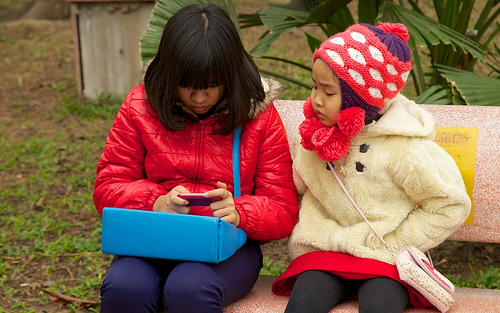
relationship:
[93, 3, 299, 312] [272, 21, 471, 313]
girl sitting next to child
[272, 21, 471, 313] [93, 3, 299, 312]
child sitting next to girl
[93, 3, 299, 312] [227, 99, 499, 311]
girl sitting on bench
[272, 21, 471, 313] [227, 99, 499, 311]
child sitting on bench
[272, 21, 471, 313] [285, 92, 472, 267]
child wearing jacket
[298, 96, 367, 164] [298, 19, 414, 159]
tie on hat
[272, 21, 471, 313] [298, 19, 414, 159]
child wearing hat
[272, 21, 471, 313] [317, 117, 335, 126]
child has chin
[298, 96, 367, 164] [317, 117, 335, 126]
tie beneath chin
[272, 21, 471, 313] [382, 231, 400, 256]
child has hand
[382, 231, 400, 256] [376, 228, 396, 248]
hand in pocket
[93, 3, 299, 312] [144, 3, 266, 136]
girl has hair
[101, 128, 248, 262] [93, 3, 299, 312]
purse on girl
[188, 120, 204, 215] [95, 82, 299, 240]
zipper zipped up on jacket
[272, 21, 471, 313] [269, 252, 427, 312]
child wearing skirt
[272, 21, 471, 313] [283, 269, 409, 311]
child wearing leggings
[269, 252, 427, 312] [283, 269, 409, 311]
skirt worn over leggings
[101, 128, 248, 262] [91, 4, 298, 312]
purse on woman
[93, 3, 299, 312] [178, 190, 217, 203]
girl holding cellphone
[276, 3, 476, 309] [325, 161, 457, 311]
child wearing purse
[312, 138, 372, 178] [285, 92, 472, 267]
buttons on jacket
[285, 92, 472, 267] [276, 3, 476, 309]
jacket on child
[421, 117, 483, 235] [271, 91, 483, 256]
sign on back of bench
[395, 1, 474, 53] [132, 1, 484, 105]
leaves on plant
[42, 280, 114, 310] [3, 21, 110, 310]
leaf laying on ground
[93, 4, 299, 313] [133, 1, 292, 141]
girl with hair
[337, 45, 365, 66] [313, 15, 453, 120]
dot on hat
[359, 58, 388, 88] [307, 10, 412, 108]
dot on hat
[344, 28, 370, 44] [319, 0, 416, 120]
dot on hat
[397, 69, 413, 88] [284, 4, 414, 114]
dot on hat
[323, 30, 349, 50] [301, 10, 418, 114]
dot on hat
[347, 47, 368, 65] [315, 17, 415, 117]
dot on hat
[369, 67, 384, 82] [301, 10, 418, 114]
dot on hat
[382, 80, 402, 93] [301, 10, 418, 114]
dot on hat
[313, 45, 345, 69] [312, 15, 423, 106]
dot on hat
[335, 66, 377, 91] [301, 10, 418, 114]
dot on hat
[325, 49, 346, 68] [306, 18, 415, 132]
dot on hat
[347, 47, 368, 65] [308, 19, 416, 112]
dot on hat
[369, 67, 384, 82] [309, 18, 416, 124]
dot on hat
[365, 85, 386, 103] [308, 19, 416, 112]
polka dot on hat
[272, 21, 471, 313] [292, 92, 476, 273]
child wearing coat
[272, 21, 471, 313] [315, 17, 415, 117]
child wearing hat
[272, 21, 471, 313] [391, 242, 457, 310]
child has bag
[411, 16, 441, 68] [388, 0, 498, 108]
leaves are on plant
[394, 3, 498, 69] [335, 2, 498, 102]
leaves are on plant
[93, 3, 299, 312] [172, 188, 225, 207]
girl looking at cell phone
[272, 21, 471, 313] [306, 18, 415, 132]
child wearing hat